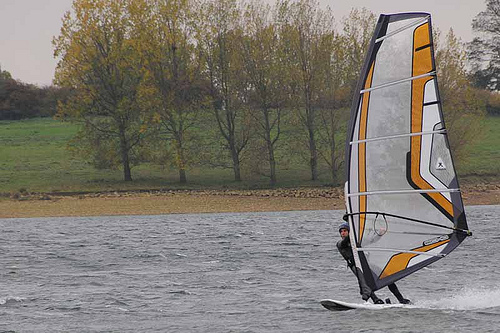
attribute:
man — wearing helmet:
[323, 223, 418, 314]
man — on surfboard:
[331, 218, 415, 312]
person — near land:
[268, 204, 423, 294]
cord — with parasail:
[341, 195, 466, 245]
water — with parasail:
[68, 205, 371, 322]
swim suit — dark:
[335, 241, 415, 306]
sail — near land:
[346, 9, 473, 296]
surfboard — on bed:
[318, 297, 420, 310]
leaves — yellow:
[63, 9, 349, 107]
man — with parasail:
[337, 223, 412, 303]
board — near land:
[316, 296, 455, 312]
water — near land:
[14, 233, 304, 326]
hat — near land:
[336, 222, 355, 237]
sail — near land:
[305, 32, 473, 319]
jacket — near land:
[334, 235, 364, 273]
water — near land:
[2, 205, 484, 331]